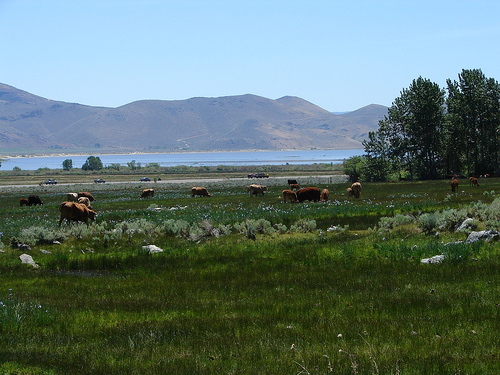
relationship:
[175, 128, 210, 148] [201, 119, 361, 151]
path in mountain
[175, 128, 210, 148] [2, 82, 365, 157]
path in hills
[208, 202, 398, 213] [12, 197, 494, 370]
flowers in field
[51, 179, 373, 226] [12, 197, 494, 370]
cows in field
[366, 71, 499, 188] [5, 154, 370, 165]
trees are next to lake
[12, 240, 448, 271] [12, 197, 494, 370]
rocks in field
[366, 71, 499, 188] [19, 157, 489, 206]
trees are in pasture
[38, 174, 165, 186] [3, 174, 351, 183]
cars are on road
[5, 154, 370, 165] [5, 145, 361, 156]
lake has shore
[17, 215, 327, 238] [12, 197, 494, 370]
scrub brush in field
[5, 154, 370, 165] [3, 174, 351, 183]
lake across road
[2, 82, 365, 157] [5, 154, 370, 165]
hills are next to lake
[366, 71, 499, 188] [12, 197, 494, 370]
trees next to field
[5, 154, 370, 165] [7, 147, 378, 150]
river at base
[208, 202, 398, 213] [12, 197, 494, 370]
flowers are in middle of field